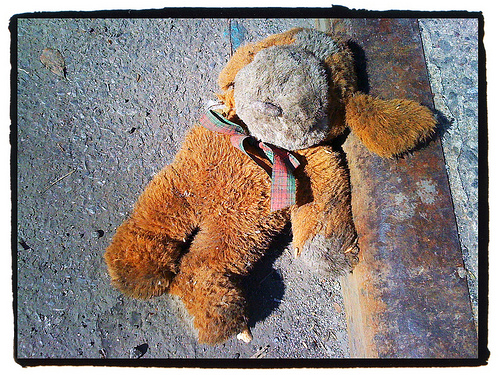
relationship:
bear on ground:
[99, 24, 429, 346] [16, 16, 480, 362]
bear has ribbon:
[99, 24, 429, 346] [195, 100, 304, 213]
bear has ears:
[99, 24, 429, 346] [226, 41, 439, 158]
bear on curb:
[99, 24, 429, 346] [330, 19, 480, 369]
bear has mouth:
[99, 24, 429, 346] [248, 99, 288, 119]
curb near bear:
[330, 19, 480, 369] [99, 24, 429, 346]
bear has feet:
[99, 24, 429, 346] [105, 221, 256, 348]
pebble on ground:
[113, 322, 262, 360] [16, 16, 480, 362]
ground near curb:
[16, 16, 480, 362] [330, 19, 480, 369]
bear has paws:
[99, 24, 429, 346] [286, 206, 366, 280]